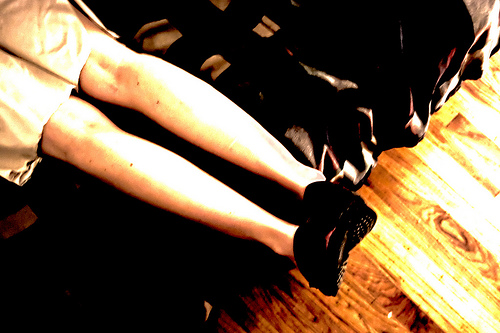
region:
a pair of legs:
[48, 48, 269, 307]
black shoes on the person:
[292, 165, 372, 300]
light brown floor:
[387, 182, 462, 279]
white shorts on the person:
[6, 5, 88, 85]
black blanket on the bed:
[229, 33, 301, 98]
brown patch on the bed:
[131, 9, 184, 52]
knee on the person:
[90, 53, 157, 97]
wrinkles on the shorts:
[37, 18, 76, 64]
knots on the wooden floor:
[415, 205, 476, 254]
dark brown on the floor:
[260, 293, 320, 325]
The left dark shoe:
[287, 222, 347, 312]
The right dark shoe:
[305, 187, 385, 232]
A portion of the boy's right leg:
[174, 169, 289, 279]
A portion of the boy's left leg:
[219, 104, 299, 204]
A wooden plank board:
[405, 155, 498, 332]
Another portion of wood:
[223, 291, 346, 332]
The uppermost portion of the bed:
[327, 0, 487, 114]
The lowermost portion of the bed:
[0, 232, 100, 331]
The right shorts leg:
[0, 62, 49, 177]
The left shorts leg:
[22, 0, 86, 78]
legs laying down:
[14, 5, 460, 330]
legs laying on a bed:
[7, 14, 404, 281]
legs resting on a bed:
[5, 12, 463, 332]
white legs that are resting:
[37, 22, 457, 312]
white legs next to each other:
[16, 16, 446, 328]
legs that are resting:
[8, 45, 394, 315]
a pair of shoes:
[219, 153, 393, 268]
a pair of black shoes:
[257, 161, 447, 307]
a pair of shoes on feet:
[189, 146, 459, 298]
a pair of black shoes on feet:
[212, 145, 465, 328]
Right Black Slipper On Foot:
[268, 178, 396, 232]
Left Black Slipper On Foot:
[278, 217, 362, 306]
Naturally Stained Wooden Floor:
[191, 121, 498, 326]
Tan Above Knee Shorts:
[0, 1, 102, 194]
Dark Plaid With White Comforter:
[89, 6, 491, 213]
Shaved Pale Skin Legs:
[22, 25, 313, 260]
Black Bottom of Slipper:
[330, 200, 380, 250]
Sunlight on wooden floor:
[337, 121, 499, 308]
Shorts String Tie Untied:
[35, 0, 170, 40]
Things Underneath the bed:
[115, 283, 265, 325]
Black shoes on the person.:
[236, 146, 431, 314]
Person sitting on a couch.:
[1, 3, 429, 331]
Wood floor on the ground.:
[340, 121, 483, 284]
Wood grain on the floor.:
[374, 180, 484, 294]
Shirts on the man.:
[1, 2, 163, 189]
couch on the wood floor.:
[229, 39, 497, 264]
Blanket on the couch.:
[242, 29, 429, 236]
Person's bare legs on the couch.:
[18, 10, 420, 323]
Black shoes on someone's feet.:
[244, 120, 386, 331]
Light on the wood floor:
[406, 152, 498, 230]